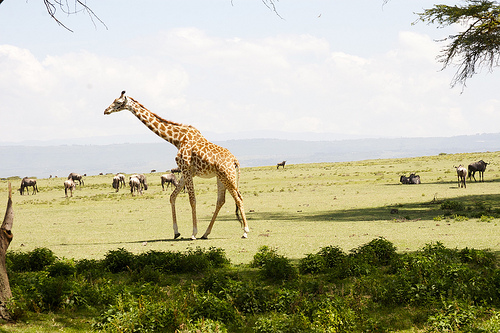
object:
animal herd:
[9, 161, 174, 191]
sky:
[53, 69, 88, 128]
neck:
[137, 104, 177, 146]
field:
[2, 181, 499, 332]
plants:
[347, 236, 407, 273]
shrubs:
[430, 259, 500, 331]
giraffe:
[101, 88, 252, 241]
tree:
[408, 1, 496, 95]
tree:
[0, 1, 109, 32]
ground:
[20, 196, 497, 331]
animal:
[100, 89, 253, 244]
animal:
[59, 177, 76, 201]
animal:
[452, 160, 469, 192]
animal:
[13, 170, 42, 198]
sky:
[273, 48, 420, 137]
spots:
[195, 153, 214, 163]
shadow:
[196, 193, 498, 221]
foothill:
[365, 129, 496, 176]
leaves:
[466, 2, 499, 22]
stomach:
[193, 166, 217, 180]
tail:
[233, 172, 254, 211]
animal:
[125, 174, 142, 197]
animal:
[272, 150, 290, 168]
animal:
[392, 164, 424, 184]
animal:
[454, 161, 474, 194]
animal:
[468, 153, 484, 183]